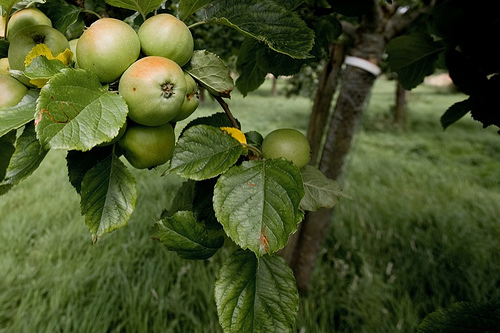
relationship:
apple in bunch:
[139, 13, 194, 68] [75, 13, 202, 170]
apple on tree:
[139, 13, 194, 68] [0, 1, 317, 333]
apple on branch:
[260, 129, 311, 173] [215, 96, 240, 130]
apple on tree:
[260, 129, 311, 173] [0, 1, 317, 333]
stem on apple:
[32, 32, 48, 45] [6, 24, 70, 89]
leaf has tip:
[212, 158, 306, 271] [252, 251, 262, 268]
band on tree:
[342, 53, 382, 77] [234, 2, 500, 296]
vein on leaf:
[264, 200, 286, 232] [212, 158, 306, 271]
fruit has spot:
[118, 55, 188, 126] [131, 84, 137, 93]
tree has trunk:
[234, 2, 500, 296] [274, 1, 397, 297]